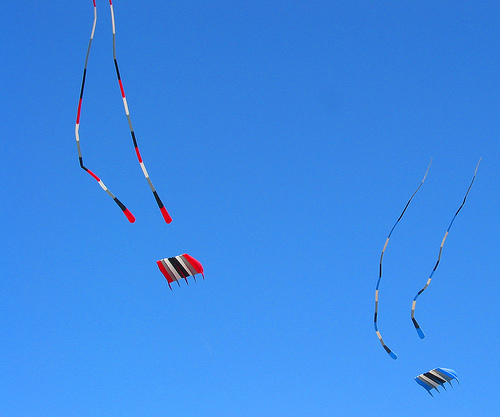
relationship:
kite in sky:
[66, 0, 211, 294] [1, 2, 498, 413]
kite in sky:
[367, 148, 488, 400] [1, 2, 498, 413]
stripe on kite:
[182, 252, 206, 274] [156, 252, 206, 288]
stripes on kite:
[432, 366, 462, 383] [20, 207, 245, 334]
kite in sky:
[66, 0, 211, 294] [2, 35, 496, 407]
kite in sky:
[367, 148, 488, 400] [2, 35, 496, 407]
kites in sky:
[74, 2, 484, 397] [5, 262, 21, 307]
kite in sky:
[70, 9, 210, 295] [1, 2, 498, 413]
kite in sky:
[367, 160, 470, 400] [1, 2, 498, 413]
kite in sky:
[367, 148, 488, 400] [141, 7, 499, 153]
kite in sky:
[66, 0, 211, 294] [141, 7, 499, 153]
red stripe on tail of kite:
[153, 205, 179, 226] [67, 0, 179, 228]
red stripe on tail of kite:
[119, 202, 138, 226] [67, 0, 179, 228]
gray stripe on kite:
[101, 186, 116, 198] [66, 0, 211, 294]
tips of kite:
[412, 145, 494, 185] [371, 307, 458, 379]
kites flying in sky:
[358, 149, 484, 403] [1, 2, 498, 413]